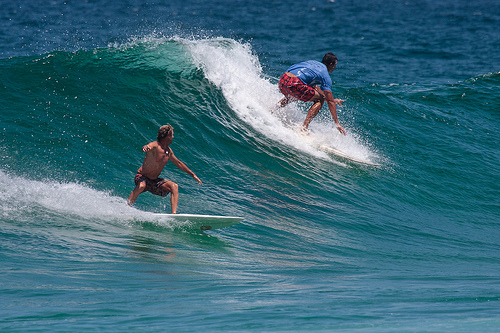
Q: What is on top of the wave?
A: The whitecap.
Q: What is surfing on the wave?
A: The man.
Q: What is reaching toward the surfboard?
A: The man.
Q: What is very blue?
A: The water.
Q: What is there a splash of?
A: The water.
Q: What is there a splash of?
A: The water.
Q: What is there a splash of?
A: The water.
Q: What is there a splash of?
A: The water.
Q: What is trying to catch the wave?
A: The surfer.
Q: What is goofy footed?
A: The surfer.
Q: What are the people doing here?
A: Surfing.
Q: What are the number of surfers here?
A: 2.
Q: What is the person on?
A: A surfboard.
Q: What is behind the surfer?
A: A wave.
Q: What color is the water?
A: Blue and white.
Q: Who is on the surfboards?
A: The men.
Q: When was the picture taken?
A: Daytime.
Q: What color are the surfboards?
A: White.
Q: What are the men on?
A: Surfboards.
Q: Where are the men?
A: On surfboards.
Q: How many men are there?
A: Two.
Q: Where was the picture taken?
A: Ocean.